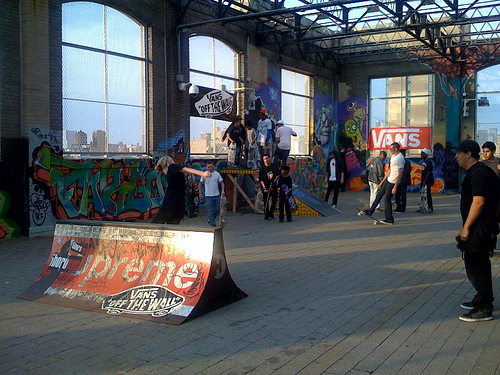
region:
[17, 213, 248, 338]
THE RAMP SAYS SUPREME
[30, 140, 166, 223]
THE GRAFFITI IS COLORFUL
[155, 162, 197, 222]
THE BOY IS WEARING A T-SHIRT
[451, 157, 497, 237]
THE MAN IS WEARING A BLACK SHIRT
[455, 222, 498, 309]
THE MAN IS WEARING BLACK PANTS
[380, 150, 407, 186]
THE MAN IS WEARING A WHITE SHIRT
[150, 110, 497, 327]
THE PEOPLE ARE GATHERED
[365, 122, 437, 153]
THE SIGN IS RED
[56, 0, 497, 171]
THE WINDOWS ARE BIG AND BRIGHT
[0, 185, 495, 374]
THE FLOOR IS BRICK AND GREY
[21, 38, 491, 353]
People are gathered in a city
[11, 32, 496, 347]
Some people are enjoying some recreation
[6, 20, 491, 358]
People are in a recreation area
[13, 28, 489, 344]
People are out in the daytime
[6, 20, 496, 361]
People are enjoying their friends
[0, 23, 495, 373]
Boys are making new friendships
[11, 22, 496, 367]
People are using their skateboards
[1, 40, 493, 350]
Skateboards are being used here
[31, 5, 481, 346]
People are inside a structure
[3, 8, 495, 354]
Boys are together having fun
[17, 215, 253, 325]
A graffiti covered ramp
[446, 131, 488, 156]
A black baseball cap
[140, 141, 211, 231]
A boy riding a skateboard on a ramp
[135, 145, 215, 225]
A boy in a black T-shirt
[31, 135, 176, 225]
Blue/green graffiti writing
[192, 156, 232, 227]
A boy holding a skateboard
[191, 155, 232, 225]
A boy in a white T-shirt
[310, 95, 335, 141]
A grey graffiti face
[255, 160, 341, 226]
A yellow/black ramp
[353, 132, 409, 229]
A man riding a skateboard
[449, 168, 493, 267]
the shirt is black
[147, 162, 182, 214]
the shirt is black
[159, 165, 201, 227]
the shirt is black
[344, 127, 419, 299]
man riding a skateboard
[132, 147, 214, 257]
man riding a skateboard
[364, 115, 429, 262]
man riding a skateboard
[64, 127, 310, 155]
city skyline through windows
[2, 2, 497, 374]
skateboarders inside building with open roof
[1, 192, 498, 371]
red and white ramp on brick floor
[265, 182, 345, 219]
ramp with black surface and yellow side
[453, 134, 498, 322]
young man wearing black clothing and baseball cap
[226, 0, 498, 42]
sky above steel girders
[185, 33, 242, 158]
black and white sign on window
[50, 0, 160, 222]
blue, green and red graffiti below window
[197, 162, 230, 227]
boy in jeans and white t-shirt carrying skateboard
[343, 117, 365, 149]
yellow face painted on far wall